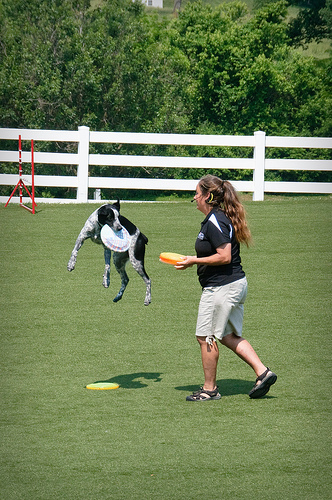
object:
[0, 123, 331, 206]
fence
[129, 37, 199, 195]
trees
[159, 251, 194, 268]
frisbee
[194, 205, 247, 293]
shirt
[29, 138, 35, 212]
pole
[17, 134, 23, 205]
pole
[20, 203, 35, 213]
pole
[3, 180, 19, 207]
pole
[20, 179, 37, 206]
pole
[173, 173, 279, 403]
woman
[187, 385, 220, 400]
foot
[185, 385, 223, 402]
sandal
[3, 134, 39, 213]
obstacle course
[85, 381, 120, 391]
frisbee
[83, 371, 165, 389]
shadow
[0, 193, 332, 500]
ground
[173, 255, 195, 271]
hands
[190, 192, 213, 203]
microphone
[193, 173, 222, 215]
head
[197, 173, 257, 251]
hair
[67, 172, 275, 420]
tricks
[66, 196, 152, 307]
dog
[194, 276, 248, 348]
shorts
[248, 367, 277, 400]
sandal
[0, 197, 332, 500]
grass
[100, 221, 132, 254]
frisbee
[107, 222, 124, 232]
mouth